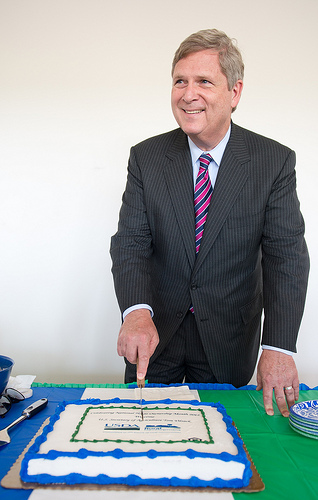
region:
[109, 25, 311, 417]
Man wearing a suit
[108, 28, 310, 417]
Person wearing a suit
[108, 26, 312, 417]
Male wearing a suit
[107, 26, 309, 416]
White male wearing a suit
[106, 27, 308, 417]
White man wearing a suit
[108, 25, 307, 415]
Caucasian man wearing a suit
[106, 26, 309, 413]
Caucasian male wearing a suit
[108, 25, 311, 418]
Man wearing a striped tie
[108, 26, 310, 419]
Man smiling wearing a suit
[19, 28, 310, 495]
Man preparing to cut a cake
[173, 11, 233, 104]
man has sandy hair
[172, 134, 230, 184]
man has blue shirt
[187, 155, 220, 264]
red and blue tie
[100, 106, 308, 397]
man has black blazer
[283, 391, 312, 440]
blue and white plates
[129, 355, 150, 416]
man is holding knife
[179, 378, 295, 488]
cake on green cloth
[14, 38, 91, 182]
white wall behind man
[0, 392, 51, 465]
spatula next to cake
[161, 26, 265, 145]
The man is smiling.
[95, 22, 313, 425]
The man is wearing a suit.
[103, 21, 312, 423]
The man is wearing a ring on his left hand.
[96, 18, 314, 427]
The man is wearing a tie.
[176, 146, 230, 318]
The tie is striped.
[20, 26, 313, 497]
The man is preparing to cut a cake.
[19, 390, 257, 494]
The cake is rectangular.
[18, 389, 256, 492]
The cake is blue, white and green.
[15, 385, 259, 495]
The cake is uneaten.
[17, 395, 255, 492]
The cake is uncut.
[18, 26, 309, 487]
Man cutting a cake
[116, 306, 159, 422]
Knife in man's hand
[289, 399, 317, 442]
Stacked plates on the table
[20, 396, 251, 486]
Sheetcake with blue and green trim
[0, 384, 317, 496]
Blue and green tablecloth on the table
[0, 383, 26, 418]
Eyeglasses on the table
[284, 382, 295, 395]
Ring on man's finger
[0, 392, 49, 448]
Spatula to left of cake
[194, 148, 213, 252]
Tie around man's neck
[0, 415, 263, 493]
Cardboard under the cake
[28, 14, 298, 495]
A man is in a house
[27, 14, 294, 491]
A man is in a room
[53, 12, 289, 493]
A man is cutting a cake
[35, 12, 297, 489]
A man is wearing a nice suit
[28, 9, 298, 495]
A man is wearing a necktie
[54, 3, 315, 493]
A man is smiling very nicely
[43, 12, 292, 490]
The man is having a celebration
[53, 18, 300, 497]
The man is enjoying his day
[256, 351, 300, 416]
old man's hand with wedding ring arched on table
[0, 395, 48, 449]
flat wedge serving utensil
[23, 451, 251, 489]
edge of square cake with white frosting edged with blue icing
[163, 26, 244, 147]
man's face with forced smile and vacant eyes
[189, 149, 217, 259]
worn blue tie with purple stripes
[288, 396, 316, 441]
stack of blue and white patterned paper plates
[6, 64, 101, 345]
dirty-white wall with faint shadows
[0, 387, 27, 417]
sunglasses lain on table reflecting ceiling